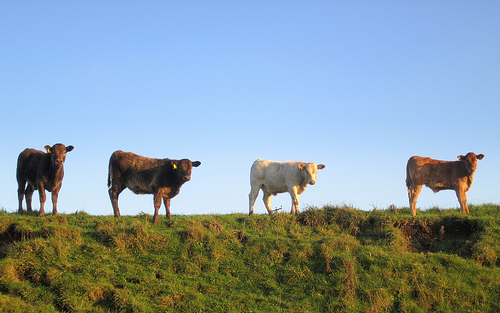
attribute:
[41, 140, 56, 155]
cow ear — brown colored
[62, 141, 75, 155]
cow ear — brown colored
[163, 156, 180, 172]
cow ear — brown colored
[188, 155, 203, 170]
cow ear — brown colored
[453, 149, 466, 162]
cow ear — brown colored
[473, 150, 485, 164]
cow ear — brown colored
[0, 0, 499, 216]
sky — cloudless, blue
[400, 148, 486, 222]
cow — brown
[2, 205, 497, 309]
grass — green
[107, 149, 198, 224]
cow — dark brown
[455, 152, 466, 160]
ear —  brown colored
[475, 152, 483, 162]
ear —  brown colored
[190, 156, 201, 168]
ear —  brown colored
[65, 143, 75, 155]
ear —  brown colored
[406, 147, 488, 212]
cow — four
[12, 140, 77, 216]
cow — brown colored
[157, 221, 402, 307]
grass — green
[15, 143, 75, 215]
cow — adult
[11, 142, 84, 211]
cow — brown colored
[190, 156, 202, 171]
ear — brown colored, cow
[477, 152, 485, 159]
ear — brown colored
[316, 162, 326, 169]
ear — brown colored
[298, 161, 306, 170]
ear — brown colored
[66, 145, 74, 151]
ear — brown colored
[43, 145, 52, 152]
ear — brown colored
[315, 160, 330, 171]
ear — brown, colored, cow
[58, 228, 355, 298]
grass — green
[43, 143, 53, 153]
brown ear — brown colored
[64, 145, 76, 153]
brown ear — brown colored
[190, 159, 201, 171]
brown ear — brown colored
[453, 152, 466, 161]
brown ear — brown colored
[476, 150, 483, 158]
brown ear — brown colored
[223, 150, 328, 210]
cow — white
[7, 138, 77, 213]
cow — adult